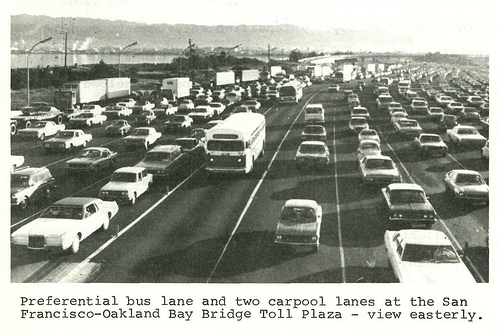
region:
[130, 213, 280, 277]
Shadow of car cast in the ground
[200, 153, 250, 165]
Headlights of bus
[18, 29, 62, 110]
Light pole on the left side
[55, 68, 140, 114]
Long truck on the left side of the road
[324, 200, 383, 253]
Shadow of car cast in the ground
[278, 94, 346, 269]
Four cars in the same lane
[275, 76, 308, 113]
Bus on the road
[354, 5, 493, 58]
Sunshine coming from the upper right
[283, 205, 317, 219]
People can be see inside the car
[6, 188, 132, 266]
White car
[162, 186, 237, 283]
empty space on roadway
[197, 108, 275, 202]
white and black commuter bus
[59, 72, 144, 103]
two cart 18 wheeler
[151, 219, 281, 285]
shadow of sedan car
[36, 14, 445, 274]
black and white photo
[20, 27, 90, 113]
tall street road lights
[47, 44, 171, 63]
large waterfront near highway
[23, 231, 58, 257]
front license plate of cadillac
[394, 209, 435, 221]
front headlight of car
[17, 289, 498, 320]
text underneath the picture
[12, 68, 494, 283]
a bridge full of traffic on a sunny day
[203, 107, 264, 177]
a bus going down the bridge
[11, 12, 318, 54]
a mountain off the the side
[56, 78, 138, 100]
a truck goind down the freeway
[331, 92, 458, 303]
a lane of cars on the freeway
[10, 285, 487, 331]
writing on the bottom of the picture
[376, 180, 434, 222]
a black car near the front of the lane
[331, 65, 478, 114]
so many cars on the bridge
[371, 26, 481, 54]
the sunny sky behind the bridge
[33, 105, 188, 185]
even more cars on the bridge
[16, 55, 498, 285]
Road full of cars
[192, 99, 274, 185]
White bus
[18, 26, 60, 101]
Light street pole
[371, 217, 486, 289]
White car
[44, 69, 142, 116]
White truck on left side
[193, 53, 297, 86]
Trucks on left side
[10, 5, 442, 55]
Mountains in the background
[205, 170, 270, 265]
Dividing lines on the road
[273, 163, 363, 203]
Shadow of car cast in the ground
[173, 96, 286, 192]
This is a white bus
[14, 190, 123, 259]
This is a white car.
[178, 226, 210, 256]
This is the street.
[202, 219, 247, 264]
this is white paint.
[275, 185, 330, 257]
this is a gray car.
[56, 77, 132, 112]
this is a white semi truck.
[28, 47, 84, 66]
this is the water.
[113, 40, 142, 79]
this is a street light.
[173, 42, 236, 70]
this is a bunch of trees.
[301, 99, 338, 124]
this is a white van.